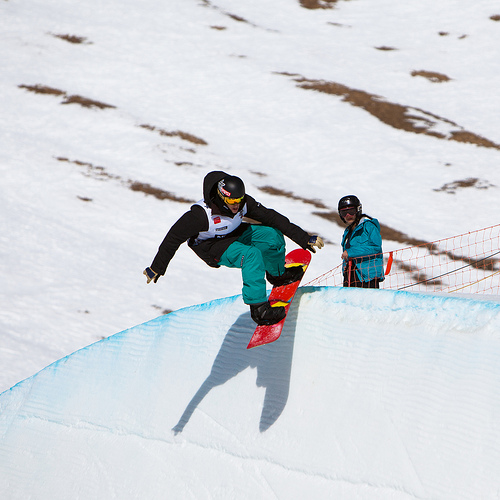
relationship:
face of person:
[212, 185, 252, 214] [150, 144, 321, 359]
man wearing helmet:
[142, 170, 328, 327] [195, 162, 252, 228]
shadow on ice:
[170, 284, 323, 437] [164, 327, 383, 440]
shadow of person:
[170, 284, 323, 437] [186, 196, 278, 303]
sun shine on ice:
[312, 352, 484, 500] [371, 394, 415, 427]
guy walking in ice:
[336, 193, 386, 291] [325, 254, 415, 286]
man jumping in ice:
[142, 170, 328, 327] [265, 240, 318, 343]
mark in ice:
[75, 122, 155, 188] [21, 55, 184, 223]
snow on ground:
[12, 56, 496, 278] [106, 99, 253, 181]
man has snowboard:
[142, 170, 328, 327] [255, 261, 320, 345]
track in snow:
[32, 105, 161, 323] [71, 201, 135, 268]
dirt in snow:
[48, 63, 454, 192] [132, 108, 214, 148]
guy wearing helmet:
[336, 193, 386, 291] [336, 195, 362, 211]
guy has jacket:
[336, 193, 386, 291] [352, 238, 379, 267]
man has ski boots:
[142, 170, 328, 327] [242, 250, 309, 324]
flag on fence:
[376, 252, 396, 272] [363, 228, 493, 304]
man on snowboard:
[142, 170, 328, 327] [258, 259, 316, 348]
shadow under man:
[182, 335, 288, 414] [153, 172, 309, 312]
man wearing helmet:
[142, 170, 328, 327] [216, 175, 246, 197]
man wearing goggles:
[142, 170, 328, 327] [228, 196, 247, 222]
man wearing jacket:
[150, 152, 329, 337] [173, 222, 237, 248]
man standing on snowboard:
[142, 170, 328, 327] [247, 248, 314, 351]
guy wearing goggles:
[336, 193, 386, 291] [337, 204, 363, 220]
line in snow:
[4, 285, 485, 404] [4, 284, 485, 498]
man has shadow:
[142, 170, 328, 327] [170, 282, 323, 433]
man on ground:
[142, 170, 328, 327] [86, 279, 440, 469]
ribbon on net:
[375, 247, 406, 279] [288, 220, 486, 305]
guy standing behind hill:
[336, 193, 386, 291] [3, 283, 475, 498]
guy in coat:
[336, 193, 386, 291] [338, 214, 386, 285]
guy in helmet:
[336, 195, 386, 293] [337, 193, 368, 225]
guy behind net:
[336, 193, 386, 291] [302, 220, 483, 301]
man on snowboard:
[142, 170, 328, 327] [247, 248, 314, 351]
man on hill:
[142, 170, 328, 327] [3, 283, 475, 498]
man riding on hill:
[142, 170, 328, 327] [3, 283, 475, 498]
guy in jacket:
[336, 193, 386, 291] [334, 215, 384, 285]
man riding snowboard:
[142, 170, 328, 327] [242, 245, 314, 348]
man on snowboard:
[142, 170, 328, 327] [242, 245, 314, 348]